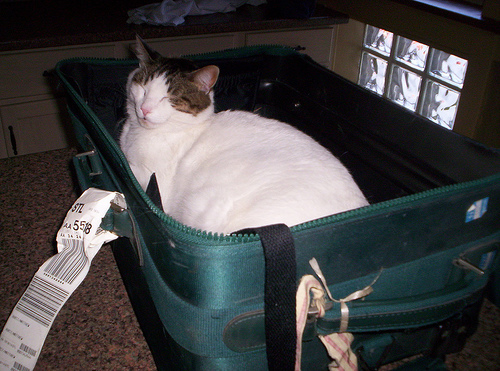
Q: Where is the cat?
A: In the suitcase.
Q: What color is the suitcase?
A: Green.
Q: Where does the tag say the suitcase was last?
A: STL.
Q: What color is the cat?
A: Brown and white.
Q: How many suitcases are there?
A: 1.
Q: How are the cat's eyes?
A: Closed.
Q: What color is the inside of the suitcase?
A: Black.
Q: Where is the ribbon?
A: On the suitcase handle.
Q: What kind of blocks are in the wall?
A: Glass.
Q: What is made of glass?
A: The wall.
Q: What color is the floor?
A: Brown.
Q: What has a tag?
A: The luggage.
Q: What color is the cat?
A: Brown black and white.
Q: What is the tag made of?
A: Paper.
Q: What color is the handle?
A: Dark green.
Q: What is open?
A: The luggage.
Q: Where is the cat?
A: In a suitcase.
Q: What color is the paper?
A: White.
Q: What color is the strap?
A: Dark blue.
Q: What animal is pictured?
A: A cat.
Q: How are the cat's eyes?
A: Closed.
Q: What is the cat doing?
A: Sleeping.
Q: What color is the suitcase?
A: Blue.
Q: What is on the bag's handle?
A: Claim tag.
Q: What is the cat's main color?
A: White.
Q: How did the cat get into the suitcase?
A: Was open.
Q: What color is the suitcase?
A: Green.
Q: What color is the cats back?
A: White.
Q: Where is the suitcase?
A: On countertop.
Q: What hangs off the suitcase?
A: A tag.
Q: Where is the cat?
A: In the suitcase.